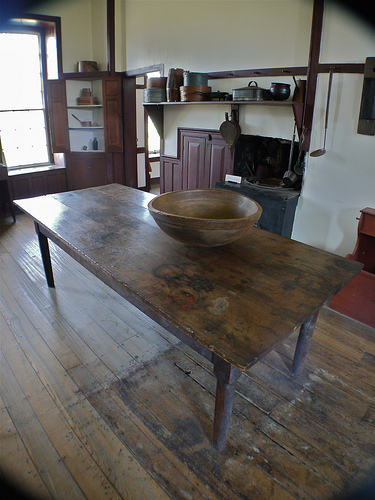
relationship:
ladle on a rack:
[306, 68, 334, 160] [187, 55, 360, 85]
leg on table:
[199, 354, 237, 462] [7, 162, 372, 460]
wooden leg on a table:
[24, 218, 68, 291] [7, 162, 372, 460]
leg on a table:
[210, 378, 237, 452] [7, 162, 372, 460]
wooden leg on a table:
[288, 309, 329, 384] [7, 162, 372, 460]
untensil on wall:
[305, 64, 340, 161] [318, 135, 366, 229]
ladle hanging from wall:
[304, 68, 339, 161] [92, 2, 373, 253]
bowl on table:
[145, 186, 263, 250] [13, 182, 364, 343]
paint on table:
[179, 293, 196, 310] [7, 162, 372, 460]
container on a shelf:
[218, 79, 269, 102] [145, 99, 284, 109]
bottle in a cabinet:
[92, 135, 101, 150] [41, 70, 134, 188]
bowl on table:
[137, 160, 273, 245] [31, 153, 147, 247]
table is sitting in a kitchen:
[7, 162, 372, 460] [2, 2, 374, 498]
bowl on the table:
[145, 186, 263, 250] [11, 184, 278, 404]